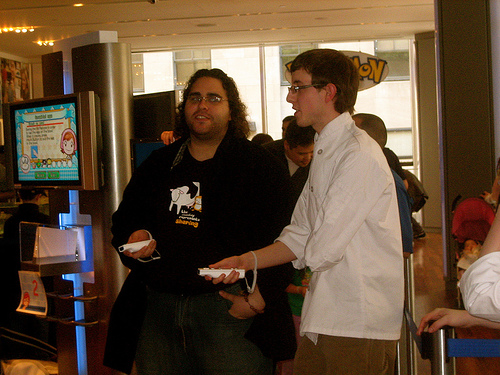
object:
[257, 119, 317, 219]
man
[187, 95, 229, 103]
eyeglasses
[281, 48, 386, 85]
pokeman logo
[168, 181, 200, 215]
cow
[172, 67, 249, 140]
hair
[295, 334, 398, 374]
pants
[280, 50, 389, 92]
sticker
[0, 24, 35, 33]
lights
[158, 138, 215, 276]
shirt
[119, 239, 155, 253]
controller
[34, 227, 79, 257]
wii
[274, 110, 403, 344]
chef jacket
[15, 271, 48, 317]
flyer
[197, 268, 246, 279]
controller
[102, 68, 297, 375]
guy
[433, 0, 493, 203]
wall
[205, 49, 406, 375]
fella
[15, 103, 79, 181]
screen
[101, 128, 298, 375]
clothing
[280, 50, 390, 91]
sign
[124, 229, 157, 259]
hand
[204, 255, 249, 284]
hand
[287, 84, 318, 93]
glasses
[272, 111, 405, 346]
shirt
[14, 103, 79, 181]
tv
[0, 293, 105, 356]
shelf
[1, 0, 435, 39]
ceiling